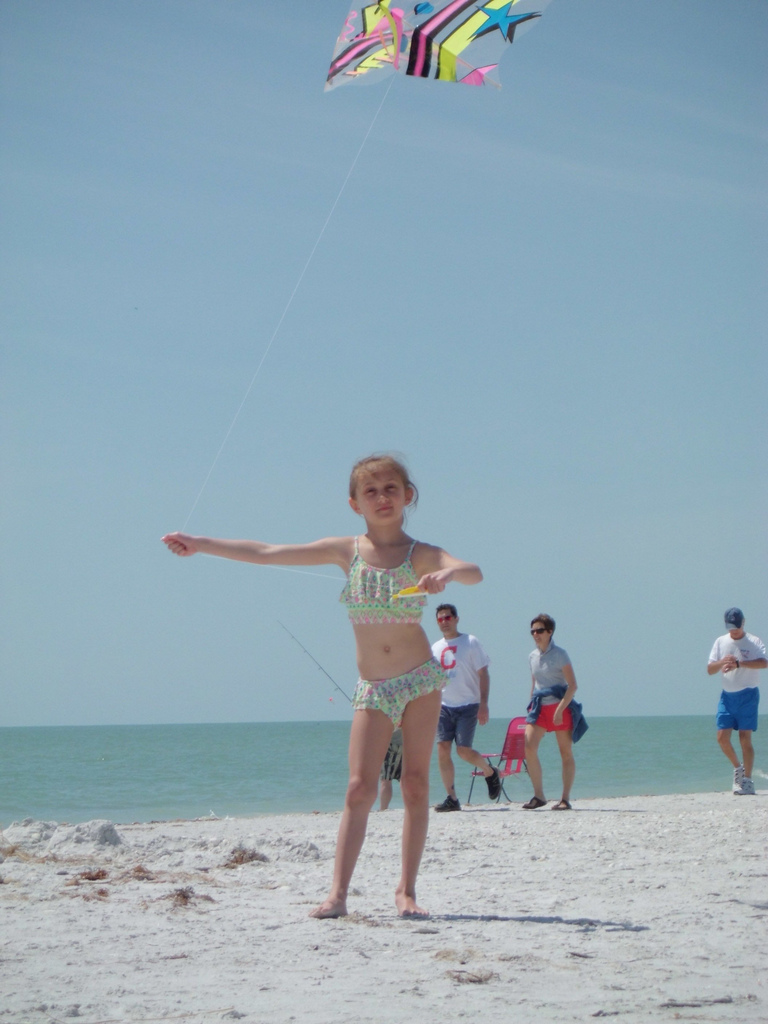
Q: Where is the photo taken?
A: At the beach.